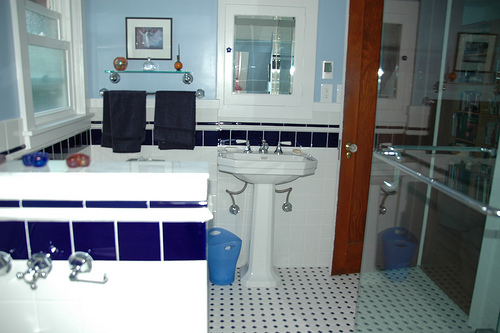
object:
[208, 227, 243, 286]
trash can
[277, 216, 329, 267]
bathroom wall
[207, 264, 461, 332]
tile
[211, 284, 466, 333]
bathroom floor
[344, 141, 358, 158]
door handle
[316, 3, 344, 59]
bathroom wall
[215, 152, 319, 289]
bathroom sink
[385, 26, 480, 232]
reflection/bathroom objects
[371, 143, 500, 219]
handle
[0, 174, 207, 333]
tiled wall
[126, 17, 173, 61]
art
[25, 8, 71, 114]
framed window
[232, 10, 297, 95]
cabinet mirror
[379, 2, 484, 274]
shower enclosure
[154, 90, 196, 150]
black towel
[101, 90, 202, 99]
rack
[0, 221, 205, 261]
tile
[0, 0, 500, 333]
bathroom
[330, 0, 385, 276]
door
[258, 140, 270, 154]
faucet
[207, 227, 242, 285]
basket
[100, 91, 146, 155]
towel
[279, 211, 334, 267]
wall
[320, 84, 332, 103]
plug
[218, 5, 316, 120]
cabinet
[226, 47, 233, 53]
handle